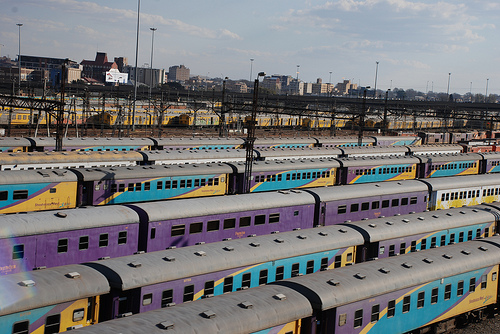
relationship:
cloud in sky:
[328, 2, 485, 29] [0, 0, 498, 96]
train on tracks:
[47, 234, 500, 334] [419, 312, 499, 332]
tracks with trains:
[14, 74, 499, 126] [0, 87, 497, 329]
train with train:
[4, 151, 482, 168] [3, 134, 425, 152]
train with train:
[3, 152, 498, 213] [3, 134, 425, 152]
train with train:
[0, 162, 500, 270] [3, 134, 425, 152]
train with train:
[47, 234, 500, 334] [3, 134, 425, 152]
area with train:
[0, 110, 466, 329] [3, 134, 425, 152]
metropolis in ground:
[8, 21, 483, 131] [405, 164, 453, 192]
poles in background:
[111, 7, 156, 143] [1, 0, 481, 125]